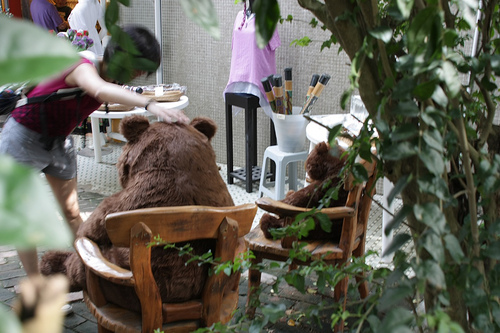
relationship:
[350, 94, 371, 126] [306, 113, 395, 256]
glass on table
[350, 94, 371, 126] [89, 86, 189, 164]
glass on table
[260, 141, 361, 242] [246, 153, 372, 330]
bear on chair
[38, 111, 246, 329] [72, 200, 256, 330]
bear on chair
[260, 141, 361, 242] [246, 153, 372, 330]
bear sitting on chair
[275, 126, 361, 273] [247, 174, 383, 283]
bear in chair